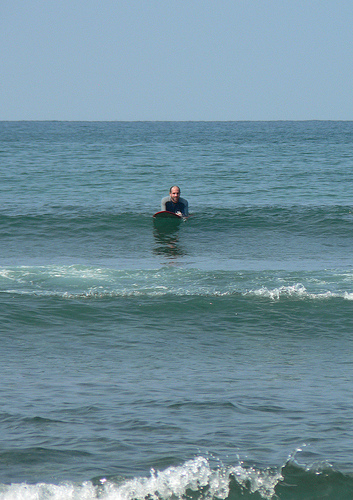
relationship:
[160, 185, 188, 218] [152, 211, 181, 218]
guy on a board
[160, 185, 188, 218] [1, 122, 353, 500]
guy in water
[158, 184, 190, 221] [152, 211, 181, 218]
guy on board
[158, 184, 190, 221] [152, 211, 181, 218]
guy laying on board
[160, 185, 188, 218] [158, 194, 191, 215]
guy wearing wet suit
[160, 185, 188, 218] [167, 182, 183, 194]
guy has a hairline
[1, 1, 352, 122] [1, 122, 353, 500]
sky over water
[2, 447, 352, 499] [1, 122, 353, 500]
wave in water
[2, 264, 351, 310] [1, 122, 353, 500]
wave in water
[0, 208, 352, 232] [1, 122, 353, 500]
ripples in water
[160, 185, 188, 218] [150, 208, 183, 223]
guy laying on a board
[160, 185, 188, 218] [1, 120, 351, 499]
guy in ocean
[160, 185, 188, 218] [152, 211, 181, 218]
guy on board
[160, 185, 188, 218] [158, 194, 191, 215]
guy wearing a wet suit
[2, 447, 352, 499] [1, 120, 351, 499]
wave in ocean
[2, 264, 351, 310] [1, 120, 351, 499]
wave in ocean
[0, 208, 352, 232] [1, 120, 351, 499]
ripples in ocean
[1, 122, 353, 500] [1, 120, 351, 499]
water in ocean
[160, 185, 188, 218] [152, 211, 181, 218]
guy sitting on board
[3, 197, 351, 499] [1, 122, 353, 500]
ripples in water